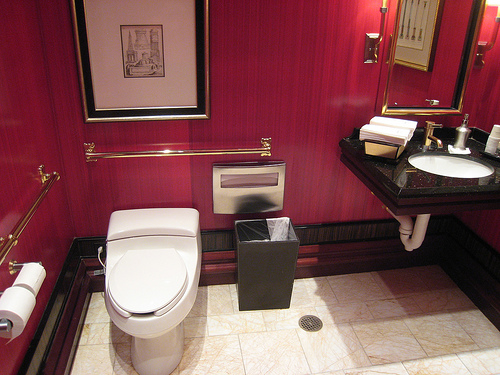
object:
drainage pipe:
[381, 202, 433, 251]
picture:
[69, 4, 206, 126]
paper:
[357, 115, 421, 145]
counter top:
[343, 122, 498, 205]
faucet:
[420, 118, 448, 151]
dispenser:
[447, 114, 475, 154]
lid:
[106, 243, 188, 313]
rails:
[81, 135, 276, 160]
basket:
[367, 142, 397, 163]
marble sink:
[335, 122, 498, 215]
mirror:
[374, 1, 485, 119]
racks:
[82, 136, 272, 163]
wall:
[211, 10, 278, 95]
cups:
[480, 122, 499, 158]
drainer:
[299, 312, 324, 331]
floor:
[70, 260, 494, 372]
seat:
[104, 248, 199, 338]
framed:
[192, 53, 214, 123]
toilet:
[180, 267, 278, 375]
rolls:
[0, 284, 37, 342]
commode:
[102, 205, 203, 374]